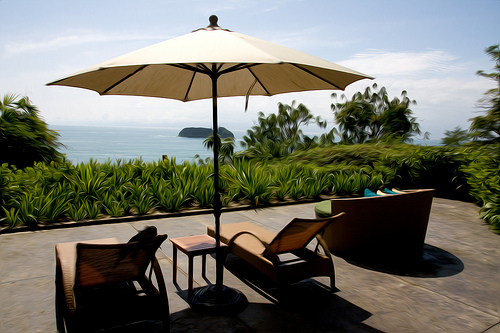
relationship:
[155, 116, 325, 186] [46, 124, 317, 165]
rock in middle ocean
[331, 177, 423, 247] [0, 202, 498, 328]
chair on porch